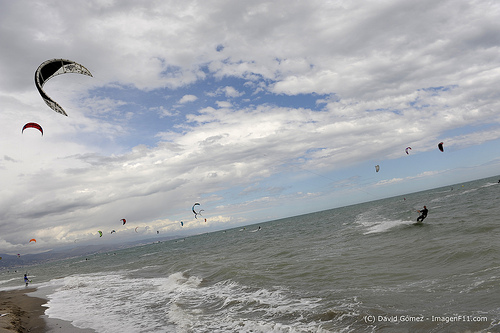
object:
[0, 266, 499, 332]
wave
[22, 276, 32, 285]
shirt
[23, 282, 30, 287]
shorts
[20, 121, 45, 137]
kite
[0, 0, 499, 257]
sky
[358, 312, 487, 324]
logo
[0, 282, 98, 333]
shore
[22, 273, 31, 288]
people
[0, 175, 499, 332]
water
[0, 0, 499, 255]
clouds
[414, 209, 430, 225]
wetsuit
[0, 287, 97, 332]
sand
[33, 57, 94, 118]
kite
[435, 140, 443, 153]
kite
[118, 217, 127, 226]
windsurfing sail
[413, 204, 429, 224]
man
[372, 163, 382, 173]
parasails